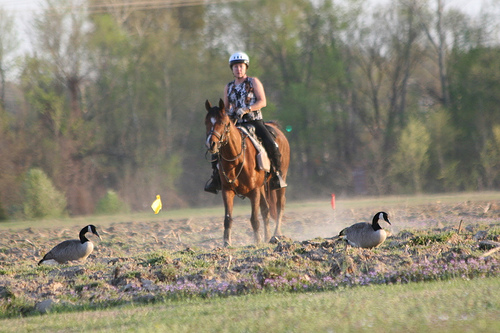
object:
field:
[3, 193, 500, 332]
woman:
[205, 52, 288, 195]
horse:
[205, 98, 291, 251]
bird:
[338, 210, 393, 251]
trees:
[0, 0, 500, 224]